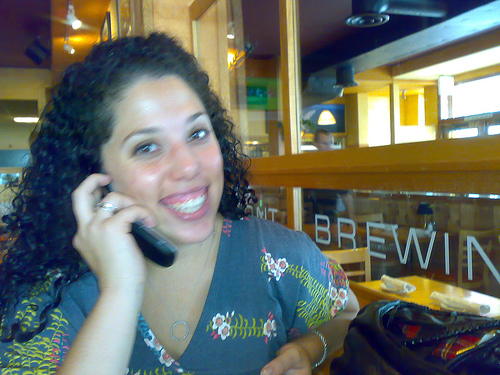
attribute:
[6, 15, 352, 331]
lady — smiling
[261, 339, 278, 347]
daisy — yellow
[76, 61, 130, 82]
hair — curly, black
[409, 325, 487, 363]
purse — large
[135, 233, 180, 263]
cell phone — black, long, here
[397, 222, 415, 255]
letter — white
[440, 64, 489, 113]
window — small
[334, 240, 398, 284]
chair — wood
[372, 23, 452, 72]
beam — brown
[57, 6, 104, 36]
light — hanging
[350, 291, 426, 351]
table — wooden, wood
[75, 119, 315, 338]
woman — young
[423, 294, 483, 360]
bag — black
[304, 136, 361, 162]
man — walking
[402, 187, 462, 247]
lamp — black